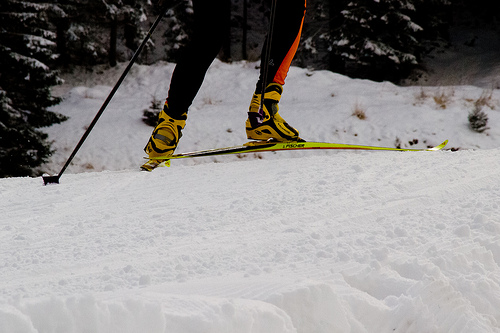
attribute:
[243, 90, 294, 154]
shoe — striped, black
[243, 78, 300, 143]
ski boot — yellow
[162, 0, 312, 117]
pants — black snow, Orange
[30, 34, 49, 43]
snow — white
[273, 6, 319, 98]
stripe — orange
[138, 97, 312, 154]
snow shoes — black snow, Two yellow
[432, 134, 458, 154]
ski — front end , bent upwards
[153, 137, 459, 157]
skis — yellow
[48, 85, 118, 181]
ski pole — Black ski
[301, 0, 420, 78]
tree — pine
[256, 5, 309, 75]
pants — orange and black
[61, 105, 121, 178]
skipole — black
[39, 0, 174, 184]
pole — thin 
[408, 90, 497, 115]
dead grass — Dead 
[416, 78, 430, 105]
plant — popping out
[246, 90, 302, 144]
snowshoe — black snow , Yellow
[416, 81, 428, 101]
grass — dead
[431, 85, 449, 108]
grass — dead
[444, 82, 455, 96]
grass — dead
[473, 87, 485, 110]
grass — dead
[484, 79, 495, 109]
grass — dead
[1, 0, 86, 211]
tree — green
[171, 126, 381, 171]
ski — striped, black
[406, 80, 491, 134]
grass patch — sparse, dead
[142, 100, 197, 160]
ski boot — yellow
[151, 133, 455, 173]
ski — Yellow 